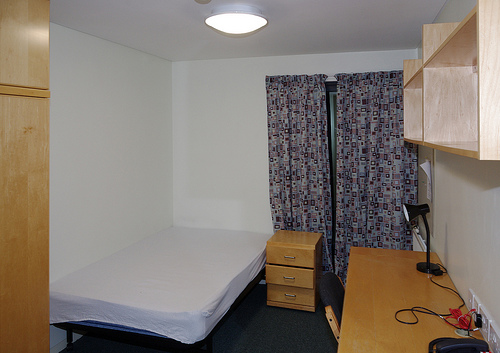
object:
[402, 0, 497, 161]
shelving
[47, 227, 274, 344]
bed sheet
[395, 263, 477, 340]
cord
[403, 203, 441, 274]
lamp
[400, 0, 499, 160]
shelf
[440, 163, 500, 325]
wall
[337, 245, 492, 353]
desk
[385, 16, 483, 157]
mans leg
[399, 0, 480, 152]
cabinet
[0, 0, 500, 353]
bedroom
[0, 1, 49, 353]
cabinet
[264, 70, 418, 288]
curtains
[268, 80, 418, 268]
window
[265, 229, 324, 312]
side table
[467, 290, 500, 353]
outlets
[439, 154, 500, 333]
wall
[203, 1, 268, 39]
light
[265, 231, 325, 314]
drawer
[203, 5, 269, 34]
ceiling light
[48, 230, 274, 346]
mattress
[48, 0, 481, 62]
ceiling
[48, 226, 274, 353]
bed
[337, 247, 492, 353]
table